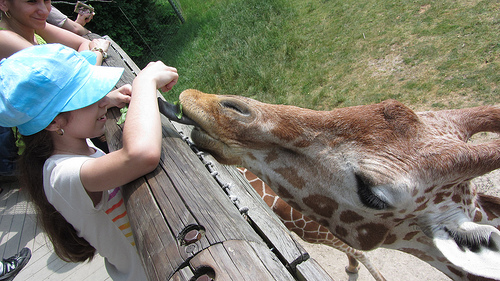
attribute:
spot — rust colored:
[262, 146, 277, 163]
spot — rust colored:
[271, 164, 306, 191]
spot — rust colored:
[275, 182, 292, 197]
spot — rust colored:
[302, 189, 339, 218]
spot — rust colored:
[414, 193, 424, 203]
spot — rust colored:
[303, 195, 338, 219]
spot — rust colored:
[337, 208, 361, 225]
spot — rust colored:
[414, 194, 427, 204]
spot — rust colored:
[452, 192, 465, 203]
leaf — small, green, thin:
[170, 97, 186, 119]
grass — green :
[168, 9, 493, 90]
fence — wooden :
[77, 32, 334, 278]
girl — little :
[0, 42, 179, 278]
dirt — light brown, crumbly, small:
[364, 62, 402, 77]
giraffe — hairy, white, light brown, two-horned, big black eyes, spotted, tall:
[188, 62, 497, 264]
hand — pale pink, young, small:
[129, 58, 180, 89]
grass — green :
[362, 42, 497, 108]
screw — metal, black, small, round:
[194, 268, 218, 278]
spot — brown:
[431, 189, 448, 204]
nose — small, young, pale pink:
[101, 97, 112, 109]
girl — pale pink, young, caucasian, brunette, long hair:
[1, 39, 163, 280]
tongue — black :
[151, 91, 196, 127]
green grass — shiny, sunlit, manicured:
[98, 3, 498, 126]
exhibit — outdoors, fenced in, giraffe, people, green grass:
[78, 0, 499, 280]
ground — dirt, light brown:
[311, 236, 444, 279]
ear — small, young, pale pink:
[38, 111, 68, 139]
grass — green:
[168, 0, 283, 97]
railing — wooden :
[78, 38, 318, 276]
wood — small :
[115, 144, 289, 257]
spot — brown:
[452, 190, 462, 204]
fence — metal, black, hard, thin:
[80, 34, 207, 259]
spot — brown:
[260, 147, 279, 165]